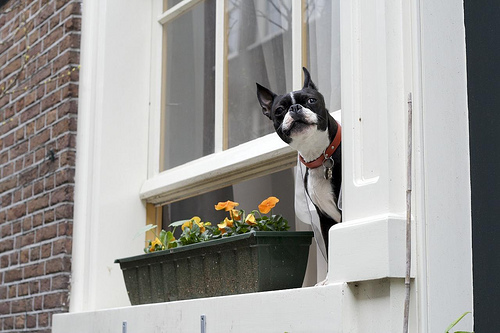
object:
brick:
[61, 13, 82, 34]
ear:
[255, 80, 278, 120]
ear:
[301, 65, 318, 93]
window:
[135, 159, 332, 273]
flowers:
[244, 211, 257, 225]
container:
[113, 228, 314, 305]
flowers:
[142, 194, 291, 256]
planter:
[113, 228, 315, 305]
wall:
[411, 0, 475, 332]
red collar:
[299, 123, 344, 171]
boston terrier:
[253, 66, 342, 286]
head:
[252, 66, 336, 159]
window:
[143, 0, 343, 182]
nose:
[287, 101, 301, 116]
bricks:
[13, 62, 67, 165]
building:
[0, 0, 492, 332]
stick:
[400, 89, 420, 331]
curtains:
[226, 4, 343, 288]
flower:
[258, 193, 280, 215]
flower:
[215, 197, 237, 209]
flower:
[178, 215, 203, 227]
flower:
[145, 234, 164, 251]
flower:
[214, 222, 230, 231]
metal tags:
[321, 160, 337, 180]